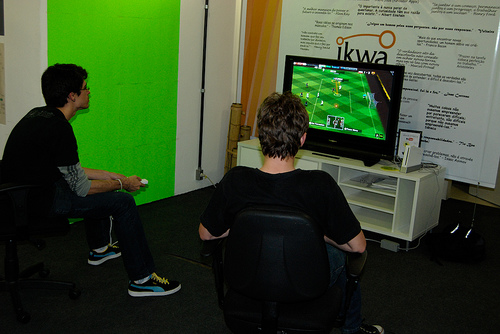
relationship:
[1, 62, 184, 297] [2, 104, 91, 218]
men wearing a shirt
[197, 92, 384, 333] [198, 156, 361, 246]
man wearing a shirt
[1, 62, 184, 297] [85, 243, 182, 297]
men wearing shoes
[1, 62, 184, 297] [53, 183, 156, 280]
men wearing jeans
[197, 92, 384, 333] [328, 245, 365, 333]
man wearing jeans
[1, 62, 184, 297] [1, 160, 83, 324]
men sitting on chair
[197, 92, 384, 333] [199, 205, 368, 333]
man sitting on chair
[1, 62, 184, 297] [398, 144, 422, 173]
men playing a game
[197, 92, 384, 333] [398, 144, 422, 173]
man playing a game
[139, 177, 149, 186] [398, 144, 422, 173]
controller for game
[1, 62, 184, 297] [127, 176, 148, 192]
men with a hand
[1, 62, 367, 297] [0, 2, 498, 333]
men in a room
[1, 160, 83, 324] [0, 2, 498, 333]
chair in room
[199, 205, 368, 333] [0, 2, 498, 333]
chair in room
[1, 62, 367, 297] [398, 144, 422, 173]
men playing game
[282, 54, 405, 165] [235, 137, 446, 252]
television on tv stand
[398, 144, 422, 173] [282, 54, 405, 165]
game next to television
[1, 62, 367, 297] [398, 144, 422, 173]
men are playing a game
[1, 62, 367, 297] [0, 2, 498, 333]
men in room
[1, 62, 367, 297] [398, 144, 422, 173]
men playing a game